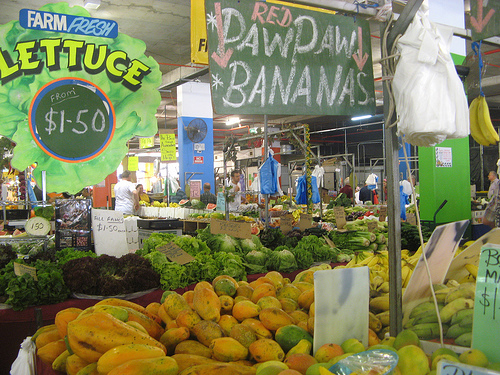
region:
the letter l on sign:
[1, 44, 19, 81]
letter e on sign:
[13, 38, 45, 77]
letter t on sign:
[37, 34, 64, 72]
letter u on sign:
[83, 39, 108, 77]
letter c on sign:
[106, 47, 127, 82]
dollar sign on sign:
[44, 107, 56, 137]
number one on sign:
[58, 104, 68, 136]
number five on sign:
[73, 106, 88, 137]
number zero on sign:
[89, 105, 108, 139]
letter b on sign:
[225, 62, 250, 117]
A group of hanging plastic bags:
[388, 9, 473, 146]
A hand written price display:
[30, 74, 117, 163]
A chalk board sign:
[205, 0, 379, 117]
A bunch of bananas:
[347, 247, 373, 267]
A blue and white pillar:
[174, 77, 216, 198]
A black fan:
[183, 116, 208, 141]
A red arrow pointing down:
[212, 2, 232, 73]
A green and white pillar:
[420, 0, 470, 223]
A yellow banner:
[188, 3, 335, 66]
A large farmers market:
[12, 3, 487, 358]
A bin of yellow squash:
[51, 292, 273, 374]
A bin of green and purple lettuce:
[9, 248, 145, 295]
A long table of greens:
[153, 229, 374, 265]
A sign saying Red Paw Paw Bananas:
[216, 59, 383, 130]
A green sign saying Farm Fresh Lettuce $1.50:
[11, 7, 166, 187]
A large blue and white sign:
[168, 72, 218, 204]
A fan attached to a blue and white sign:
[178, 116, 213, 146]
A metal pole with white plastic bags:
[373, 19, 419, 346]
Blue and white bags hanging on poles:
[243, 132, 385, 207]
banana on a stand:
[435, 278, 477, 305]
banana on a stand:
[435, 311, 480, 336]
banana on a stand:
[402, 309, 437, 330]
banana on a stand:
[362, 261, 392, 283]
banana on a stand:
[462, 231, 499, 249]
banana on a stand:
[342, 246, 367, 263]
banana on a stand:
[447, 331, 474, 343]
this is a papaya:
[52, 267, 179, 374]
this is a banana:
[466, 75, 498, 152]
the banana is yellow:
[463, 82, 499, 144]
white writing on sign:
[198, 5, 371, 118]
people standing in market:
[86, 144, 305, 225]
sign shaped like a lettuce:
[11, 7, 173, 195]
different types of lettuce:
[18, 211, 373, 299]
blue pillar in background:
[175, 84, 228, 194]